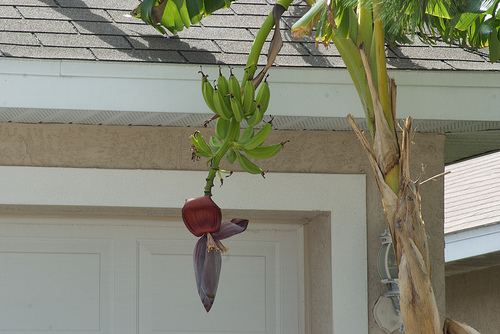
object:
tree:
[129, 0, 500, 334]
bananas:
[189, 63, 291, 187]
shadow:
[0, 0, 500, 71]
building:
[0, 0, 499, 334]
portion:
[0, 57, 499, 122]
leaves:
[130, 0, 229, 37]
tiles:
[442, 59, 500, 70]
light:
[371, 225, 430, 334]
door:
[0, 204, 333, 334]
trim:
[0, 166, 369, 333]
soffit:
[0, 107, 500, 134]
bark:
[347, 42, 451, 334]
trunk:
[331, 0, 444, 334]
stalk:
[241, 0, 293, 89]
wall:
[0, 121, 443, 169]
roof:
[444, 150, 500, 235]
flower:
[182, 195, 249, 313]